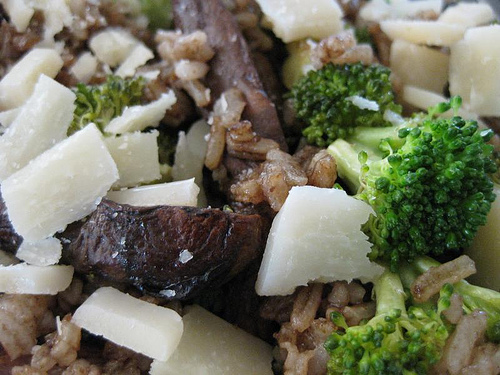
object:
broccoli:
[261, 55, 498, 375]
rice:
[170, 84, 287, 188]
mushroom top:
[98, 217, 204, 283]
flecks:
[347, 80, 412, 135]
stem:
[330, 135, 379, 178]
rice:
[306, 28, 372, 68]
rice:
[155, 27, 212, 106]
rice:
[280, 285, 344, 364]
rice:
[437, 293, 497, 374]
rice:
[410, 251, 476, 300]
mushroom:
[49, 200, 274, 302]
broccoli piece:
[325, 93, 499, 271]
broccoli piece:
[321, 260, 453, 373]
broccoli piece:
[282, 60, 399, 149]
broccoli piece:
[62, 72, 152, 136]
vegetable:
[0, 61, 193, 301]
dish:
[39, 51, 471, 349]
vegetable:
[270, 57, 500, 375]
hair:
[321, 302, 342, 319]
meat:
[180, 2, 282, 122]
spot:
[174, 248, 193, 264]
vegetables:
[51, 297, 283, 375]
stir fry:
[0, 0, 500, 372]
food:
[0, 1, 484, 371]